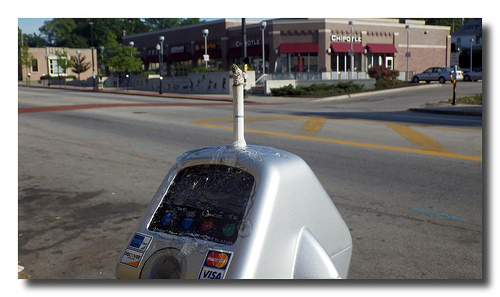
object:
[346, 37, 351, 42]
o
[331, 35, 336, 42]
letter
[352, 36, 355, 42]
t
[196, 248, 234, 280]
logo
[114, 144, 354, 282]
machine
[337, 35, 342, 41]
letter h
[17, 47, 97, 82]
building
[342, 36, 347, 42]
p